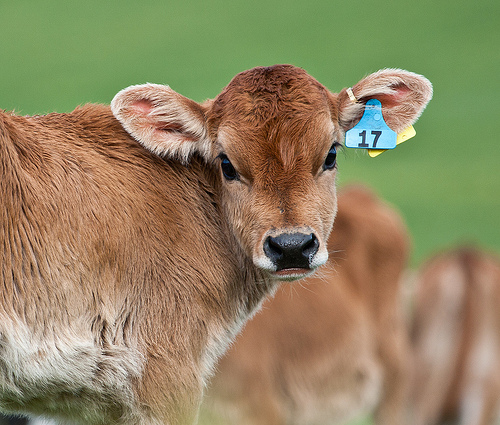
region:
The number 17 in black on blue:
[356, 124, 383, 151]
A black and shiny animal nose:
[266, 237, 322, 266]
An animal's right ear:
[101, 84, 203, 168]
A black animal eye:
[213, 150, 250, 192]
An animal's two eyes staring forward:
[213, 146, 340, 186]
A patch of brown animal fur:
[41, 180, 176, 276]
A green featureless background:
[321, 20, 444, 61]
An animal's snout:
[248, 176, 331, 288]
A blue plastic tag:
[346, 103, 401, 151]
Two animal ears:
[96, 59, 483, 176]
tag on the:
[341, 84, 420, 161]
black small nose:
[260, 230, 321, 268]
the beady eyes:
[216, 141, 340, 186]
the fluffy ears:
[111, 66, 434, 169]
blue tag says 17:
[342, 97, 397, 147]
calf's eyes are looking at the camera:
[217, 140, 341, 183]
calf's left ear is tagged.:
[336, 68, 432, 145]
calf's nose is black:
[261, 227, 321, 271]